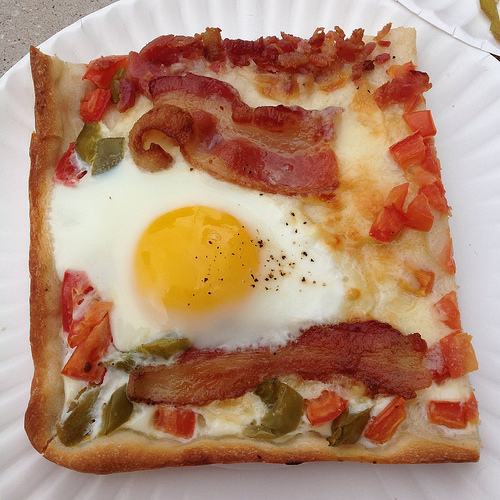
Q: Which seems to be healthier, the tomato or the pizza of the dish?
A: The tomato is healthier than the pizza.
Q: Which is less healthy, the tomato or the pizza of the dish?
A: The pizza is less healthy than the tomato.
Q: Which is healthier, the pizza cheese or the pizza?
A: The cheese is healthier than the pizza.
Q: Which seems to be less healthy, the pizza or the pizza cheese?
A: The pizza is less healthy than the cheese.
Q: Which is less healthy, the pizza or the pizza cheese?
A: The pizza is less healthy than the cheese.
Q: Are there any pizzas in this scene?
A: Yes, there is a pizza.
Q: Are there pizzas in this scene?
A: Yes, there is a pizza.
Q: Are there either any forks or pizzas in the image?
A: Yes, there is a pizza.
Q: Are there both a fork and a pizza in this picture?
A: No, there is a pizza but no forks.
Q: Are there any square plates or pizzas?
A: Yes, there is a square pizza.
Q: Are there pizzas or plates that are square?
A: Yes, the pizza is square.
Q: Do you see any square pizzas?
A: Yes, there is a square pizza.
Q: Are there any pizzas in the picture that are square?
A: Yes, there is a pizza that is square.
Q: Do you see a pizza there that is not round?
A: Yes, there is a square pizza.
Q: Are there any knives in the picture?
A: No, there are no knives.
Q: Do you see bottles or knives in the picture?
A: No, there are no knives or bottles.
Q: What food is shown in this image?
A: The food is a pizza.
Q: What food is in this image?
A: The food is a pizza.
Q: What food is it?
A: The food is a pizza.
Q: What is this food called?
A: This is a pizza.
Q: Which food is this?
A: This is a pizza.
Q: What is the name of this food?
A: This is a pizza.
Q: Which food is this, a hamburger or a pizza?
A: This is a pizza.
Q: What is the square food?
A: The food is a pizza.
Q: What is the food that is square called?
A: The food is a pizza.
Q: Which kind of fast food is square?
A: The fast food is a pizza.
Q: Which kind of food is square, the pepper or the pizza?
A: The pizza is square.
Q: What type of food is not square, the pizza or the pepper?
A: The pepper is not square.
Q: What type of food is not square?
A: The food is a pepper.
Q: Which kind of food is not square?
A: The food is a pepper.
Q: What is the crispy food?
A: The food is a pizza.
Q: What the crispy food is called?
A: The food is a pizza.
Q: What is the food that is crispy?
A: The food is a pizza.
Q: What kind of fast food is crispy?
A: The fast food is a pizza.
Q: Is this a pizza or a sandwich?
A: This is a pizza.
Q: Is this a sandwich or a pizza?
A: This is a pizza.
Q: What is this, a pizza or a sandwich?
A: This is a pizza.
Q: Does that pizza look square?
A: Yes, the pizza is square.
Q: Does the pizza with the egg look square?
A: Yes, the pizza is square.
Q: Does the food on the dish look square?
A: Yes, the pizza is square.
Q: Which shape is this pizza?
A: The pizza is square.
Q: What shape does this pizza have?
A: The pizza has square shape.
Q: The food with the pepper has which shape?
A: The pizza is square.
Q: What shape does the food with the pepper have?
A: The pizza has square shape.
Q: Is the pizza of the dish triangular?
A: No, the pizza is square.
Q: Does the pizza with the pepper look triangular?
A: No, the pizza is square.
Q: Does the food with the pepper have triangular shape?
A: No, the pizza is square.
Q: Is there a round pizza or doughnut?
A: No, there is a pizza but it is square.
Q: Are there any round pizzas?
A: No, there is a pizza but it is square.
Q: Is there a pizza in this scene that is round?
A: No, there is a pizza but it is square.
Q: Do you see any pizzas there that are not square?
A: No, there is a pizza but it is square.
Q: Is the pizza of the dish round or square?
A: The pizza is square.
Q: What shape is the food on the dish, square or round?
A: The pizza is square.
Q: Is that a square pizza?
A: Yes, that is a square pizza.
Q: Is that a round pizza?
A: No, that is a square pizza.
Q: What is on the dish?
A: The pizza is on the dish.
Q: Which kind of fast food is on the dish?
A: The food is a pizza.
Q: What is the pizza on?
A: The pizza is on the dish.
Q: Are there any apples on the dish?
A: No, there is a pizza on the dish.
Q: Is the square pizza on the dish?
A: Yes, the pizza is on the dish.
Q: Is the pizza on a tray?
A: No, the pizza is on the dish.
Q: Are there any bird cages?
A: No, there are no bird cages.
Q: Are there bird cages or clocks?
A: No, there are no bird cages or clocks.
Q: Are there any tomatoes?
A: Yes, there is a tomato.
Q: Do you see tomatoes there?
A: Yes, there is a tomato.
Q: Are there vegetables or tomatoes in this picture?
A: Yes, there is a tomato.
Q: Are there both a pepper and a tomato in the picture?
A: Yes, there are both a tomato and a pepper.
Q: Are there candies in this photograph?
A: No, there are no candies.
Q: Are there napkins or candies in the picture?
A: No, there are no candies or napkins.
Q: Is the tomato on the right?
A: Yes, the tomato is on the right of the image.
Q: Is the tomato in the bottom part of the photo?
A: No, the tomato is in the top of the image.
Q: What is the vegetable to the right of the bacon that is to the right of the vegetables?
A: The vegetable is a tomato.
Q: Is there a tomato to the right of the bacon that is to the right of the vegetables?
A: Yes, there is a tomato to the right of the bacon.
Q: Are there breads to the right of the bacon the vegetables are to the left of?
A: No, there is a tomato to the right of the bacon.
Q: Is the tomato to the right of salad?
A: No, the tomato is to the right of the bacon.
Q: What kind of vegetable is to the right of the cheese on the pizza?
A: The vegetable is a tomato.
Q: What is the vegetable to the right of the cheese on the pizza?
A: The vegetable is a tomato.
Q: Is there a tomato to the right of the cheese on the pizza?
A: Yes, there is a tomato to the right of the cheese.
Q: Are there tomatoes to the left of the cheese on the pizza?
A: No, the tomato is to the right of the cheese.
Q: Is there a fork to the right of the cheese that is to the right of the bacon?
A: No, there is a tomato to the right of the cheese.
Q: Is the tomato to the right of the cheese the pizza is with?
A: Yes, the tomato is to the right of the cheese.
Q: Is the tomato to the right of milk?
A: No, the tomato is to the right of the cheese.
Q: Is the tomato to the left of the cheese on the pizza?
A: No, the tomato is to the right of the cheese.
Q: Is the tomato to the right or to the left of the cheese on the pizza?
A: The tomato is to the right of the cheese.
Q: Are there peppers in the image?
A: Yes, there is a pepper.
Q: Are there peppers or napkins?
A: Yes, there is a pepper.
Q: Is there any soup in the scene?
A: No, there is no soup.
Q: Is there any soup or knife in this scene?
A: No, there are no soup or knives.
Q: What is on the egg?
A: The pepper is on the egg.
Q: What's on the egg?
A: The pepper is on the egg.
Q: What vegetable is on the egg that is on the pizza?
A: The vegetable is a pepper.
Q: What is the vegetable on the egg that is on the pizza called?
A: The vegetable is a pepper.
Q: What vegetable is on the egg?
A: The vegetable is a pepper.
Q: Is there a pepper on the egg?
A: Yes, there is a pepper on the egg.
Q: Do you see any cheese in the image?
A: Yes, there is cheese.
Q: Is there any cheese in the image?
A: Yes, there is cheese.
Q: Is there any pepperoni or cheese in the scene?
A: Yes, there is cheese.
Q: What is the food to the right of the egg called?
A: The food is cheese.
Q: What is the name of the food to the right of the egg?
A: The food is cheese.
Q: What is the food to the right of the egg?
A: The food is cheese.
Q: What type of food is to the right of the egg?
A: The food is cheese.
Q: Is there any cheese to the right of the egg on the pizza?
A: Yes, there is cheese to the right of the egg.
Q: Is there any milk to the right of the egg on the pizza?
A: No, there is cheese to the right of the egg.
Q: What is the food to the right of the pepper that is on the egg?
A: The food is cheese.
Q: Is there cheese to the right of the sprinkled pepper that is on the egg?
A: Yes, there is cheese to the right of the pepper.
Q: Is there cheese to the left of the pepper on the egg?
A: No, the cheese is to the right of the pepper.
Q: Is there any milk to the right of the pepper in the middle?
A: No, there is cheese to the right of the pepper.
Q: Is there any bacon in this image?
A: Yes, there is bacon.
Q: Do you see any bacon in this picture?
A: Yes, there is bacon.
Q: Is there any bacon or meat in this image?
A: Yes, there is bacon.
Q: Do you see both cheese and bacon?
A: Yes, there are both bacon and cheese.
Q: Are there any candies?
A: No, there are no candies.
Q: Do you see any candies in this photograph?
A: No, there are no candies.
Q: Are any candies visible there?
A: No, there are no candies.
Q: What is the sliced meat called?
A: The meat is bacon.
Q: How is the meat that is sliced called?
A: The meat is bacon.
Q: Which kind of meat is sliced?
A: The meat is bacon.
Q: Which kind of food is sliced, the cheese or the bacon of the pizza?
A: The bacon is sliced.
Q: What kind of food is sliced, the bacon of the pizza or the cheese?
A: The bacon is sliced.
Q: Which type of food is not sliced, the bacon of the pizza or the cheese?
A: The cheese is not sliced.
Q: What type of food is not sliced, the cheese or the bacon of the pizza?
A: The cheese is not sliced.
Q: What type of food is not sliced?
A: The food is cheese.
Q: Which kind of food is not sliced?
A: The food is cheese.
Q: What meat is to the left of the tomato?
A: The meat is bacon.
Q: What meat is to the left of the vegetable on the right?
A: The meat is bacon.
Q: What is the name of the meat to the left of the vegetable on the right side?
A: The meat is bacon.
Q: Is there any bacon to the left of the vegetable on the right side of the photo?
A: Yes, there is bacon to the left of the tomato.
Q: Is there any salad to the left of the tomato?
A: No, there is bacon to the left of the tomato.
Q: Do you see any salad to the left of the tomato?
A: No, there is bacon to the left of the tomato.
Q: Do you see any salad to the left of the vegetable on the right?
A: No, there is bacon to the left of the tomato.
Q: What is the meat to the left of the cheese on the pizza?
A: The meat is bacon.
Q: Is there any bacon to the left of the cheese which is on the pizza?
A: Yes, there is bacon to the left of the cheese.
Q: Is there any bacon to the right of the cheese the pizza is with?
A: No, the bacon is to the left of the cheese.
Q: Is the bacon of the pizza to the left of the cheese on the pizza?
A: Yes, the bacon is to the left of the cheese.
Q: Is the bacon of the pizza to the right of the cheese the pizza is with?
A: No, the bacon is to the left of the cheese.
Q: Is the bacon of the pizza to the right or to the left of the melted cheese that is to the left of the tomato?
A: The bacon is to the left of the cheese.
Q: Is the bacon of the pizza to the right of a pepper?
A: Yes, the bacon is to the right of a pepper.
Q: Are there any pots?
A: No, there are no pots.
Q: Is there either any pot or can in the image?
A: No, there are no pots or cans.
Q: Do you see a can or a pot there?
A: No, there are no pots or cans.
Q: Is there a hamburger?
A: No, there are no hamburgers.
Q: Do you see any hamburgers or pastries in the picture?
A: No, there are no hamburgers or pastries.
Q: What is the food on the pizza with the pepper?
A: The food is an egg.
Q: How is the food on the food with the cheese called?
A: The food is an egg.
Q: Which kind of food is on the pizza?
A: The food is an egg.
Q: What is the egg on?
A: The egg is on the pizza.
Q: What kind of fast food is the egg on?
A: The egg is on the pizza.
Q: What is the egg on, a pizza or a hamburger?
A: The egg is on a pizza.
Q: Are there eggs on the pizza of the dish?
A: Yes, there is an egg on the pizza.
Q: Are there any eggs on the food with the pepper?
A: Yes, there is an egg on the pizza.